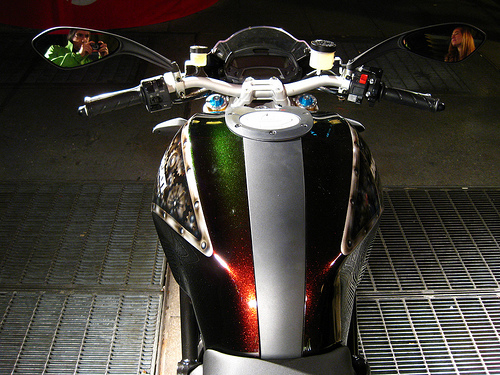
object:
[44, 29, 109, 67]
man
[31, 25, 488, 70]
mirror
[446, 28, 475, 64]
woman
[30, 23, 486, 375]
motorcycle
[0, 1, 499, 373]
street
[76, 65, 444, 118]
handlebars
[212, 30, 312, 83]
meter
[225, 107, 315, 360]
tank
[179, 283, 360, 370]
shocks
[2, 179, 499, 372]
grill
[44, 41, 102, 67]
jacket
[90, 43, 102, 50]
camera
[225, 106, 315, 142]
cap